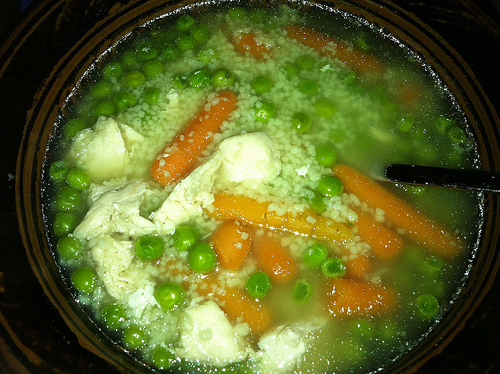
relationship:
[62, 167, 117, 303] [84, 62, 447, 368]
peas together with pasta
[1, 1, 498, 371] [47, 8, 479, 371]
bowl of broth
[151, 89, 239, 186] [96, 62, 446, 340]
carrot in soup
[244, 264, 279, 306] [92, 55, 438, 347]
pea in mixture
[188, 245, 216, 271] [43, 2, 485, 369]
pea in mixture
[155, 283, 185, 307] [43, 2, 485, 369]
pea in mixture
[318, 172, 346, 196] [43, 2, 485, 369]
pea in mixture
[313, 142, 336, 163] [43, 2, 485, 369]
pea in mixture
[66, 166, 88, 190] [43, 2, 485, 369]
pea in mixture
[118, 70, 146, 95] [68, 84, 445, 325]
pea in mixture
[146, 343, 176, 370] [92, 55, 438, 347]
pea in mixture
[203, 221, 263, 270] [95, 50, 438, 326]
carrot in soup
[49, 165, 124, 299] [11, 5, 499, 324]
peas around bowl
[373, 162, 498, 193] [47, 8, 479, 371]
spoon handle over broth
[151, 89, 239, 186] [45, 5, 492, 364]
carrot in broth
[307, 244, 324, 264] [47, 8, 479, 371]
peas in broth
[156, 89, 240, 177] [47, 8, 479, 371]
carrot in broth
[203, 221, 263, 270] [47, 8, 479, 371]
carrot in broth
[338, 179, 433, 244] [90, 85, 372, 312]
carrot in soup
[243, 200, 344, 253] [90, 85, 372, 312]
carrot in soup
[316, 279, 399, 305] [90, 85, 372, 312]
carrot in soup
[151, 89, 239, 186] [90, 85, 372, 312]
carrot in soup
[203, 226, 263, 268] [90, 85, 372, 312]
carrot in soup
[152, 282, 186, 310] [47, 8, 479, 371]
pea are in broth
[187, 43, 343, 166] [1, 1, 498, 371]
peas are inside bowl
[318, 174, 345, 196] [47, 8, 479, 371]
pea inside broth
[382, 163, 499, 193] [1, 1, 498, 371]
spoon leaning on bowl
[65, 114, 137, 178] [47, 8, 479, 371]
chunk inside broth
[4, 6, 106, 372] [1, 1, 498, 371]
stripes are on bowl